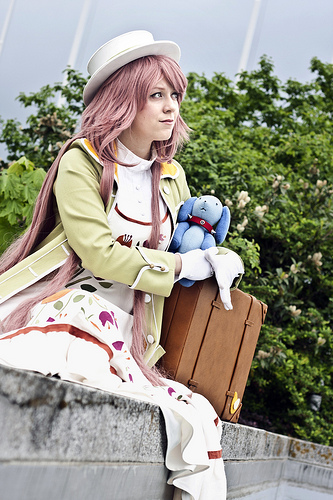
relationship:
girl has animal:
[21, 31, 265, 409] [170, 189, 230, 290]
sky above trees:
[2, 4, 330, 83] [6, 79, 330, 422]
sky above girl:
[2, 4, 330, 83] [21, 31, 265, 409]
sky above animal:
[2, 4, 330, 83] [170, 189, 230, 290]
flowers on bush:
[234, 189, 252, 212] [185, 55, 330, 443]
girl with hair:
[0, 31, 244, 499] [79, 57, 154, 164]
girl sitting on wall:
[0, 31, 244, 499] [4, 365, 331, 493]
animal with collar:
[170, 192, 230, 285] [185, 212, 216, 233]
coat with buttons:
[0, 141, 189, 367] [144, 334, 154, 343]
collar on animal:
[186, 213, 216, 236] [170, 192, 230, 285]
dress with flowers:
[2, 135, 226, 498] [98, 309, 120, 328]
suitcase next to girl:
[162, 278, 268, 418] [1, 53, 245, 383]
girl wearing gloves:
[0, 31, 244, 499] [174, 243, 246, 299]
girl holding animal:
[0, 31, 244, 499] [170, 189, 230, 290]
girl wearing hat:
[21, 31, 265, 409] [78, 25, 194, 86]